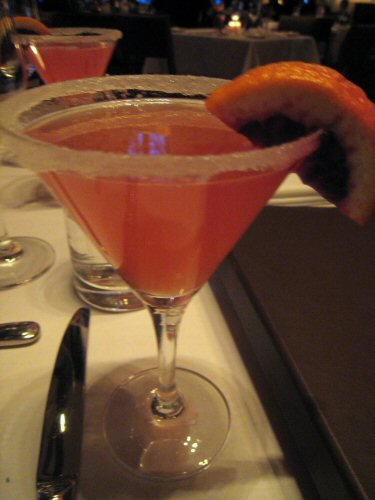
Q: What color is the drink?
A: Orange.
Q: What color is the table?
A: White.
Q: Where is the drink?
A: On the table.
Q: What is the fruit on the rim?
A: Blood orange.